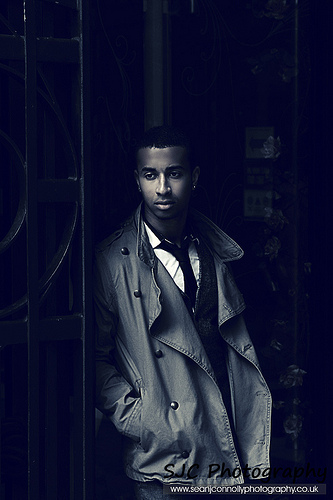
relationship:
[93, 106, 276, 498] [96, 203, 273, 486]
male wearing coat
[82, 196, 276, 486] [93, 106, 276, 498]
coat on male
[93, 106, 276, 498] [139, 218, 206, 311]
male wearing shirt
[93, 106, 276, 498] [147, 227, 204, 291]
male wearing shirt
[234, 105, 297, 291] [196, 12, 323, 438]
reflections on glass door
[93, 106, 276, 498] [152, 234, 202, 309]
male wearing tie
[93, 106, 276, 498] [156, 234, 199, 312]
male wearing necktie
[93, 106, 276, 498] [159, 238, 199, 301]
male wears tie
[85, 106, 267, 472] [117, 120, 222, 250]
male has head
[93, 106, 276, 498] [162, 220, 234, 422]
male has vest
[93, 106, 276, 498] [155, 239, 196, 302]
male has tie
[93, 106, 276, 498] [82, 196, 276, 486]
male has coat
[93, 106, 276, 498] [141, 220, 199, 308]
male wearing shirt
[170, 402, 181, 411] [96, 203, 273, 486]
button is on coat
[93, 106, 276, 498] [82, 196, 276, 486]
male wearing coat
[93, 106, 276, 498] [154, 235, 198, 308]
male wearing tie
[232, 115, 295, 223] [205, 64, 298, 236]
sign on glass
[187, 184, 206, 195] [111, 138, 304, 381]
earring in man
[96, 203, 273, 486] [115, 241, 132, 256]
coat has button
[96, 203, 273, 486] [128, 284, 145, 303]
coat has button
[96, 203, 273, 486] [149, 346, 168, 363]
coat has button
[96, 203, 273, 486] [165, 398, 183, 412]
coat has button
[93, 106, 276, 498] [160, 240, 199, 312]
male wearing necktie